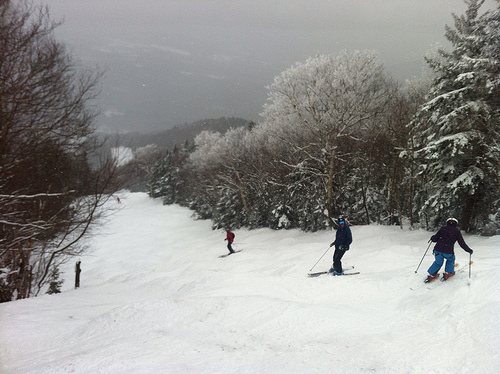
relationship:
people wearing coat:
[225, 227, 235, 255] [226, 231, 233, 242]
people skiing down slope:
[225, 227, 235, 255] [158, 257, 274, 311]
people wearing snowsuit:
[225, 227, 235, 255] [227, 230, 235, 250]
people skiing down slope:
[225, 227, 235, 255] [10, 186, 495, 372]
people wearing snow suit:
[225, 227, 235, 255] [227, 233, 235, 250]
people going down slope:
[225, 227, 235, 255] [10, 186, 495, 372]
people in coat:
[225, 227, 235, 255] [226, 231, 233, 242]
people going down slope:
[225, 227, 235, 255] [136, 252, 302, 329]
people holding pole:
[427, 217, 473, 280] [464, 253, 474, 287]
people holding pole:
[427, 217, 473, 280] [414, 237, 435, 275]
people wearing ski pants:
[427, 217, 473, 280] [422, 245, 465, 276]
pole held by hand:
[469, 253, 472, 277] [469, 245, 475, 256]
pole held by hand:
[415, 240, 433, 274] [431, 230, 435, 238]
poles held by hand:
[310, 246, 331, 271] [329, 237, 334, 244]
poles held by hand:
[310, 246, 331, 271] [339, 243, 346, 250]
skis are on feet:
[309, 264, 362, 281] [311, 260, 400, 295]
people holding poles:
[427, 217, 473, 280] [415, 237, 434, 269]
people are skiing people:
[332, 213, 353, 274] [426, 216, 473, 282]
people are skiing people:
[223, 224, 235, 252] [426, 216, 473, 282]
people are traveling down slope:
[427, 217, 473, 280] [10, 186, 495, 372]